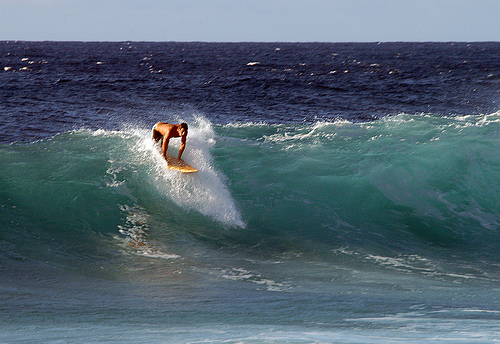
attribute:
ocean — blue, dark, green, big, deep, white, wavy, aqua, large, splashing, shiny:
[14, 47, 497, 311]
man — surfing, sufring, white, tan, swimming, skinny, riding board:
[153, 117, 194, 151]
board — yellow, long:
[163, 162, 198, 180]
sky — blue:
[21, 3, 469, 38]